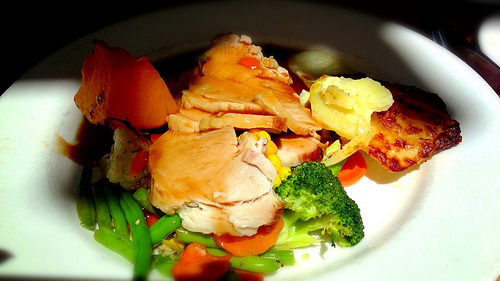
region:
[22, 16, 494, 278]
dinner on a white plate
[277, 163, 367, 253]
bright green broccoli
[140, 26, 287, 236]
turkey with gravy on top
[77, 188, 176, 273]
bright green green beans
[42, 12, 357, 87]
dark shadow cast on plate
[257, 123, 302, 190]
yellow corn under turkey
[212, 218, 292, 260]
orange carrot under turkey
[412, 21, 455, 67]
silver fork peeping out from behind plate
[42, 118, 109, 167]
brown turkey on plate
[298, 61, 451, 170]
slightly burnt potatoes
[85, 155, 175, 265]
Several green beans on plate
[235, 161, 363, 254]
Piece of broccoli on plate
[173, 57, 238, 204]
Pieces of white meat on plate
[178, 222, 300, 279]
Pieces of carrots mixed in with vegetables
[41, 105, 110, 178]
Brown sauce on the back of plate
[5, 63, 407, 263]
Plate is white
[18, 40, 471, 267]
White plate is circular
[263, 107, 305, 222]
Pieces of corn under the meat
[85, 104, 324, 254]
Mixed vegetables on plate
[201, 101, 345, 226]
Pieces of corn are yellow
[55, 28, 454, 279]
Food on a plate.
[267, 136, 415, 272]
Broccoli on the plate.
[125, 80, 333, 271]
Meat on the plate.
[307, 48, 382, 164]
White cauliflower on the plate.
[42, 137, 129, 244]
Green beans on the plate.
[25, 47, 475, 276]
White plate with food.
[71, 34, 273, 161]
Orange carrot on the plate.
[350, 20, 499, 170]
Shadow on the plate.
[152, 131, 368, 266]
Colorful veggies on the plate.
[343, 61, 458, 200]
Burnt parts of the food.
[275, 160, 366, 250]
Large piece of broccoli on a plate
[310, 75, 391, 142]
Side of potato on a plate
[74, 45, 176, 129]
Carrot slices on a plate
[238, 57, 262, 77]
Tomato portion on a plate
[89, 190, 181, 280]
Leafy greens on a dinner plate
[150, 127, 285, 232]
Chicken portion on a plate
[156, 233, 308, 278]
Portion of vegetables on a plate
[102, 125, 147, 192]
Side of squash on a plate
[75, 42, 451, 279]
Dinner portion on a plate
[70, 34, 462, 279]
Main dinner course on a plate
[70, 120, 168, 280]
green beans of a casserole on a white plate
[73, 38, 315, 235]
white meat portion of meal on a white plate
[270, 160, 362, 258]
broccoli portion of meal on a white plate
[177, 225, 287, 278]
carrot potion of the meal on the white plate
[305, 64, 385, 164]
potato portion of the meal on a white plate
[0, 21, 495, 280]
white plate which contains a healthy meal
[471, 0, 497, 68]
A piece of a plate or bowl next to the white plate containing food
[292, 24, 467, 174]
identified part of the meal appears to be cheesy toast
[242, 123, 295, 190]
corn section of meal on white plate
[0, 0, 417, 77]
dark shadow partially covering plate and food